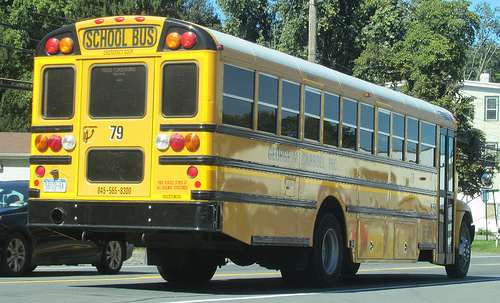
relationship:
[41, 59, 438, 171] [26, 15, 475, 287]
windows on bus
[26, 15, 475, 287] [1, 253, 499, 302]
bus in lot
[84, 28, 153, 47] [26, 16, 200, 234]
words on back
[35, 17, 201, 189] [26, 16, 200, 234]
lights on back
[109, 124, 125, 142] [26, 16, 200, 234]
number on back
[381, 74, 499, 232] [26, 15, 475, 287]
building near bus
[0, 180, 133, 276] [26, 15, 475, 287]
car near bus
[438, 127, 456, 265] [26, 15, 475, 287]
door on bus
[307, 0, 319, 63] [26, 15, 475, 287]
pole near bus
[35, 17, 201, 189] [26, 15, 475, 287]
lights on bus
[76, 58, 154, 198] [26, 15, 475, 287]
exit on bus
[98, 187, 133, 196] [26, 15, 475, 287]
number on bus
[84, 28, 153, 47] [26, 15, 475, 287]
words on bus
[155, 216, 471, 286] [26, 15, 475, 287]
wheels on bus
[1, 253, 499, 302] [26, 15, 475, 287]
lot near bus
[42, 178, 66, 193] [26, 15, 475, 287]
plate on bus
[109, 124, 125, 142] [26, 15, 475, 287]
number on bus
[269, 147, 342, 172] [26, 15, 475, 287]
school on bus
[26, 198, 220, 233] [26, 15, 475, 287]
bumper of bus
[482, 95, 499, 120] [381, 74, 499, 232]
window on building